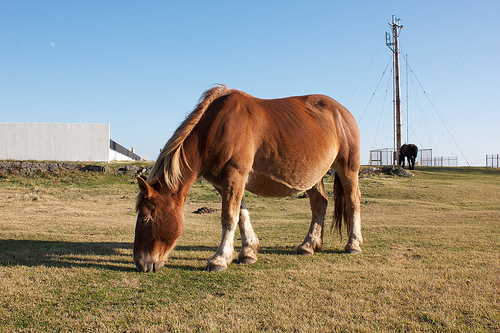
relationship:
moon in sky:
[46, 39, 58, 49] [98, 50, 170, 101]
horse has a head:
[107, 90, 370, 259] [125, 177, 182, 275]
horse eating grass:
[133, 82, 361, 273] [135, 270, 199, 301]